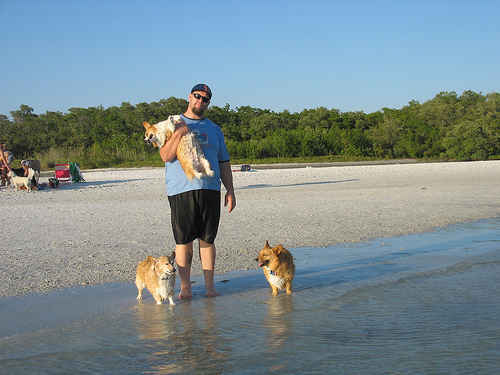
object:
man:
[157, 83, 237, 299]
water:
[4, 214, 500, 374]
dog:
[141, 113, 216, 180]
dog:
[255, 241, 296, 295]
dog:
[135, 252, 178, 305]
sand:
[0, 159, 500, 297]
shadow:
[197, 236, 488, 290]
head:
[136, 116, 158, 146]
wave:
[334, 253, 499, 326]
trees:
[449, 89, 499, 165]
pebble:
[75, 275, 90, 286]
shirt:
[163, 112, 231, 195]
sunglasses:
[189, 91, 208, 105]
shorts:
[167, 188, 221, 245]